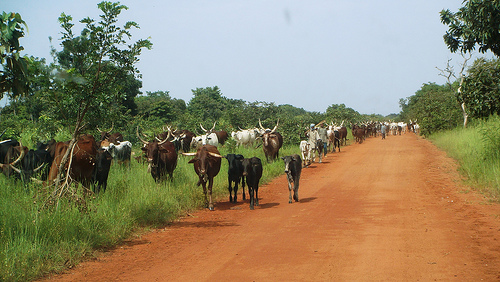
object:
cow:
[47, 134, 106, 194]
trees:
[0, 1, 148, 138]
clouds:
[218, 66, 256, 88]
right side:
[399, 0, 500, 202]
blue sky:
[0, 0, 498, 116]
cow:
[199, 118, 219, 145]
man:
[381, 124, 386, 140]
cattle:
[352, 126, 365, 144]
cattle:
[372, 126, 376, 137]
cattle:
[326, 124, 341, 153]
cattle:
[300, 140, 310, 168]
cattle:
[199, 121, 227, 147]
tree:
[437, 53, 472, 128]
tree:
[399, 82, 460, 135]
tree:
[461, 57, 500, 121]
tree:
[438, 0, 500, 58]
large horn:
[340, 120, 345, 127]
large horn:
[209, 152, 224, 158]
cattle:
[0, 137, 47, 176]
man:
[307, 123, 320, 160]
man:
[317, 122, 328, 157]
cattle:
[397, 125, 402, 135]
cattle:
[412, 119, 419, 134]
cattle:
[391, 123, 398, 136]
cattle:
[334, 120, 347, 145]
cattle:
[244, 157, 263, 211]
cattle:
[258, 119, 281, 159]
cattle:
[231, 130, 255, 148]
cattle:
[222, 154, 245, 203]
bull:
[182, 145, 224, 212]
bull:
[137, 126, 178, 183]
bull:
[334, 119, 347, 146]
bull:
[258, 117, 283, 163]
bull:
[200, 121, 229, 145]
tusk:
[259, 118, 266, 129]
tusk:
[272, 117, 279, 133]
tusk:
[210, 117, 217, 132]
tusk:
[340, 120, 344, 127]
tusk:
[136, 123, 149, 146]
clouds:
[374, 25, 430, 40]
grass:
[2, 144, 301, 282]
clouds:
[173, 19, 396, 78]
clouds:
[158, 34, 349, 99]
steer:
[97, 122, 111, 142]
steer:
[11, 143, 51, 187]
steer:
[0, 143, 26, 175]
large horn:
[238, 126, 244, 131]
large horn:
[259, 118, 266, 131]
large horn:
[106, 120, 115, 134]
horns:
[258, 118, 265, 130]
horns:
[158, 129, 171, 145]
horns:
[32, 162, 46, 172]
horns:
[209, 120, 217, 132]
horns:
[106, 121, 115, 133]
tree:
[324, 103, 360, 127]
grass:
[425, 113, 499, 195]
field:
[0, 126, 354, 282]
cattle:
[281, 154, 302, 204]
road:
[23, 126, 500, 282]